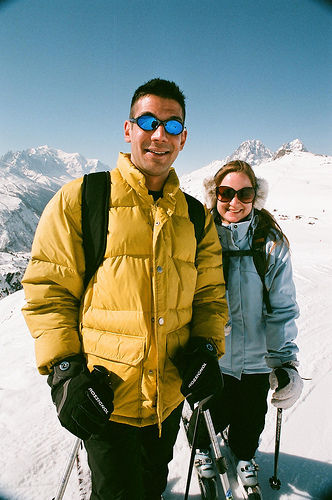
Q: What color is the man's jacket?
A: Yellow.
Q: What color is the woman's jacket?
A: Blue.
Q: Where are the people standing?
A: In the mountains.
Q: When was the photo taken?
A: During the daytime.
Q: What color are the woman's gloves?
A: White.